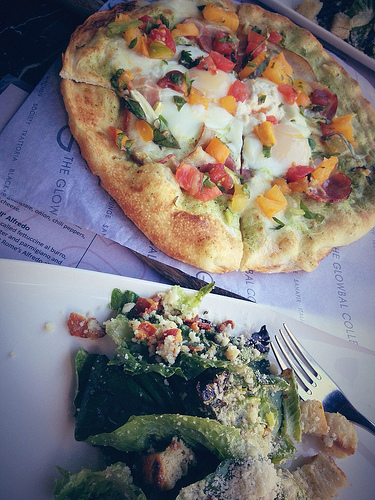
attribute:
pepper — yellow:
[251, 183, 292, 222]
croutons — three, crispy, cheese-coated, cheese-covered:
[283, 446, 351, 494]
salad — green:
[61, 289, 350, 498]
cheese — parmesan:
[224, 458, 280, 496]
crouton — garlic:
[294, 396, 331, 437]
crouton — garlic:
[316, 404, 357, 458]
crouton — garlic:
[290, 447, 347, 498]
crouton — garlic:
[133, 430, 199, 492]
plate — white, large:
[0, 257, 373, 497]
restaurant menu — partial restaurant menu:
[1, 210, 73, 263]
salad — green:
[48, 272, 350, 498]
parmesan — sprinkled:
[219, 389, 291, 498]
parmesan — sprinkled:
[138, 318, 259, 359]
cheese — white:
[133, 315, 183, 355]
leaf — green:
[110, 313, 277, 383]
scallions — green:
[289, 196, 329, 224]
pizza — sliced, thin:
[51, 3, 374, 283]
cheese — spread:
[148, 86, 285, 188]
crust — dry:
[60, 78, 243, 273]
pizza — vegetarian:
[70, 14, 371, 259]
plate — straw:
[126, 243, 231, 297]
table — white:
[7, 240, 369, 498]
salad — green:
[69, 275, 295, 457]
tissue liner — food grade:
[0, 132, 371, 342]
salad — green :
[92, 338, 319, 498]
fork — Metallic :
[259, 319, 371, 433]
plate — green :
[223, 291, 373, 385]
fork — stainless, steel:
[261, 320, 363, 437]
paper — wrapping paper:
[6, 101, 90, 232]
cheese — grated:
[222, 387, 282, 490]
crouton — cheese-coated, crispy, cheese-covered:
[299, 401, 329, 442]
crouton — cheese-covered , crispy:
[329, 412, 354, 449]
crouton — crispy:
[303, 453, 350, 491]